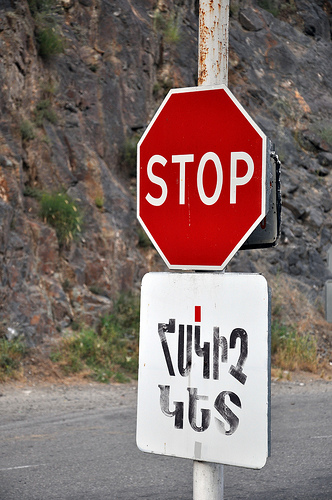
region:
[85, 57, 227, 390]
these are signs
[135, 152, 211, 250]
this is a stop sign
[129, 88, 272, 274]
the sign is red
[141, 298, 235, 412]
the sign is foreign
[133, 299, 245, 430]
the sign is white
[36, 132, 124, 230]
the cliffs are rocky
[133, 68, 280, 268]
red and white stop sign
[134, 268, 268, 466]
rectangular white sign below stop sign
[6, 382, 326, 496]
grey concrete road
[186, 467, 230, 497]
white metal pole supporting street signs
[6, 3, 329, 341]
gray rocky wall next to road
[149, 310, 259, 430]
black lettering on white sign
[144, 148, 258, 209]
white stop sign letters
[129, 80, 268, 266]
red octagon sign trimmed in white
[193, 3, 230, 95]
rusted part of white metal pole supporting signs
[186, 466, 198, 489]
the view of a white wall and chairs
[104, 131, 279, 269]
red and white stop sign on a pole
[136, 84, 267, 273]
Red and white 'stop' sign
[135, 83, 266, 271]
Stop sign on pole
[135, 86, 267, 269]
red stop sign on pole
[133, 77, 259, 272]
red stop sign on rusted pole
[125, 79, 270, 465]
two sign on rusted pole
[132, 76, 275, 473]
two signs on white pole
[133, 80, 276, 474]
two signs on rusted sign pole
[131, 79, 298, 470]
Three sign on white pole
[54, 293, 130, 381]
Grass along the side of road